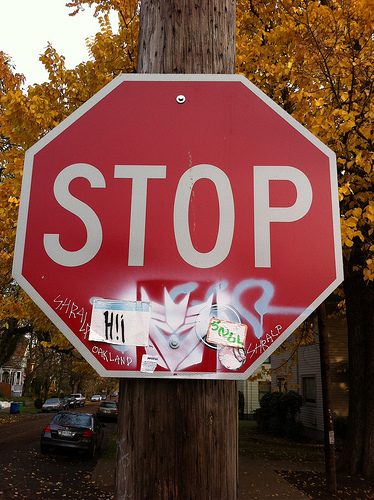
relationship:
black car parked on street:
[41, 414, 107, 458] [2, 395, 104, 496]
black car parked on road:
[41, 414, 107, 458] [0, 402, 118, 496]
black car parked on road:
[42, 408, 103, 452] [0, 402, 118, 496]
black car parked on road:
[41, 414, 107, 458] [0, 394, 116, 498]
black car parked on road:
[41, 414, 107, 458] [9, 444, 40, 486]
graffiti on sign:
[90, 277, 308, 367] [11, 52, 358, 411]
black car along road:
[41, 414, 107, 458] [1, 385, 150, 497]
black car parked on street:
[41, 414, 107, 458] [5, 401, 115, 498]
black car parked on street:
[41, 414, 107, 458] [0, 393, 120, 498]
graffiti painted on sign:
[90, 277, 308, 367] [8, 68, 346, 376]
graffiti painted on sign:
[107, 277, 271, 368] [8, 68, 346, 376]